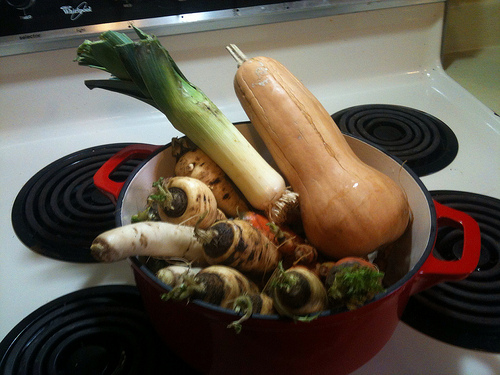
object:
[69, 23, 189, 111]
stem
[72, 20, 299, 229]
leek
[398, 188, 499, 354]
burner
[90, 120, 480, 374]
pot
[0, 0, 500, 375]
stove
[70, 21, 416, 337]
vegetable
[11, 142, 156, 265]
burner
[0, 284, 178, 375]
burner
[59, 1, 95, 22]
logo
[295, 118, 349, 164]
ground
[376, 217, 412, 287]
shadow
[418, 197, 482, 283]
handle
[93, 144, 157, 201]
handle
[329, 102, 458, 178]
burner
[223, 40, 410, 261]
squash